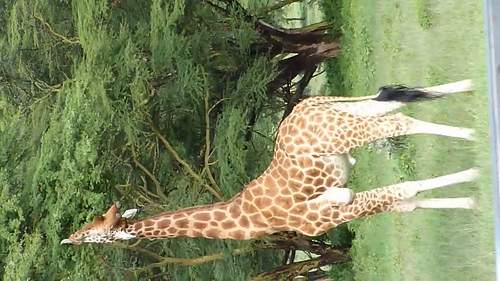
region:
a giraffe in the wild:
[37, 70, 478, 268]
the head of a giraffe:
[56, 196, 133, 258]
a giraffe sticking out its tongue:
[50, 196, 142, 256]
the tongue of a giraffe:
[55, 235, 68, 250]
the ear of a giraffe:
[115, 228, 137, 244]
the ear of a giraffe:
[121, 203, 143, 221]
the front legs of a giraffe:
[367, 163, 480, 220]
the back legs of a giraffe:
[356, 75, 481, 150]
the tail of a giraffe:
[305, 81, 442, 108]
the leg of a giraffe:
[394, 193, 474, 213]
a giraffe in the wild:
[41, 74, 481, 266]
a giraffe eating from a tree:
[56, 67, 489, 252]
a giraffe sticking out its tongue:
[32, 69, 494, 259]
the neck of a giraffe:
[140, 182, 253, 251]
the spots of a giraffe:
[283, 124, 323, 191]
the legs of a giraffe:
[362, 69, 489, 231]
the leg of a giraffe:
[423, 167, 484, 184]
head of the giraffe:
[60, 203, 138, 257]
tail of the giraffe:
[308, 85, 441, 105]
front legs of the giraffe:
[360, 168, 477, 216]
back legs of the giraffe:
[336, 80, 474, 145]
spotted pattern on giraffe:
[282, 170, 316, 220]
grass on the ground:
[383, 239, 455, 266]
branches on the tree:
[108, 176, 167, 206]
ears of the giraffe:
[110, 202, 142, 246]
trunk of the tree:
[276, 25, 357, 70]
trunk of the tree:
[268, 237, 353, 262]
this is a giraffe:
[46, 70, 468, 245]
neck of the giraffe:
[128, 207, 267, 237]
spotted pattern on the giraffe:
[277, 158, 312, 216]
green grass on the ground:
[395, 238, 477, 272]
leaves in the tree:
[14, 60, 95, 196]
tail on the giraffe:
[316, 83, 430, 105]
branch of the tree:
[84, 250, 271, 268]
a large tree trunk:
[225, 12, 352, 74]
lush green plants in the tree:
[58, 115, 135, 181]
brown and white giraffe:
[72, 84, 422, 251]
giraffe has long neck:
[114, 143, 331, 250]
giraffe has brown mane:
[117, 193, 211, 240]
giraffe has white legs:
[377, 105, 479, 225]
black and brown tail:
[308, 80, 423, 120]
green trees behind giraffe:
[0, 24, 291, 272]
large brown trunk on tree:
[254, 27, 341, 71]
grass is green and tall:
[388, 45, 458, 90]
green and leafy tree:
[44, 31, 186, 213]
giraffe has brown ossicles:
[94, 200, 135, 250]